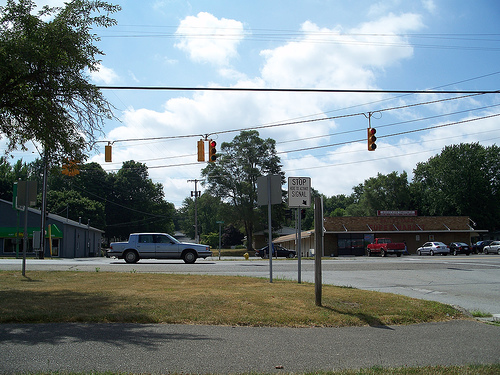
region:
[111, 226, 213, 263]
old gray car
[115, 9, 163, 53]
white clouds in blue sky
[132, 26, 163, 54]
white clouds in blue sky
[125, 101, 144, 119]
white clouds in blue sky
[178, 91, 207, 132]
white clouds in blue sky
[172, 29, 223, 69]
white clouds in blue sky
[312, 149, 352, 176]
white clouds in blue sky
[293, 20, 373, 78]
white clouds in blue sky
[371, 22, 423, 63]
white clouds in blue sky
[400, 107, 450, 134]
white clouds in blue sky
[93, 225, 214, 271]
The car is driving on the road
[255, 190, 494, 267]
Cars are parked at a business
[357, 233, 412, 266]
The truck is red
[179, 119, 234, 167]
The traffic light indicates red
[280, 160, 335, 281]
Sign indicates Stop Here to Activate Signal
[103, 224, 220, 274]
The car is light blue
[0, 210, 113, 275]
The building is a light blue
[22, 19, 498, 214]
The sky is partly cloudy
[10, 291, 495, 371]
A walkway is in the middle of the grass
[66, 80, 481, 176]
Power lines hang overhead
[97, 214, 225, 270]
A side view of a car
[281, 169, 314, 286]
A traffic sign in the foreground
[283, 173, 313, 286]
The traffic sign is white in color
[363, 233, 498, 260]
Cars in the background are parked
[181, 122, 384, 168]
Traffic lights are yellow in color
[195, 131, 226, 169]
Traffic light is on red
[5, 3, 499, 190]
The sky is cloudy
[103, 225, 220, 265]
The car is silver is color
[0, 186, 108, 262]
A gray building in the background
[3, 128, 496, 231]
Tall trees in the background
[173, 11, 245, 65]
a white cloud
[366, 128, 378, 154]
a yellow street light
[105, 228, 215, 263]
a small white car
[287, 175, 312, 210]
a black and white sign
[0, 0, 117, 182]
part of a green tree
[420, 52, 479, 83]
part of a blue sky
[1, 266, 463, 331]
a section of green grass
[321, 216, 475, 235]
the roof of a building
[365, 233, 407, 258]
a red truck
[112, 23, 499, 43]
a long electrical power line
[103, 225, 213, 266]
car waiting at stoplight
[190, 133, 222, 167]
stoplight is red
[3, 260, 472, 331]
barren brown patch of grass on side of road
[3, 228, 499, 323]
road with only one car driving on it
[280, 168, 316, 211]
Sign saying Stop wait for signal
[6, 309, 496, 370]
an asphalt walkway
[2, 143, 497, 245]
trees in distance are green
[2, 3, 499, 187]
sky is partly cloudy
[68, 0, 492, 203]
clouds are big and puffy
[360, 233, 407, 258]
res truck parked at store